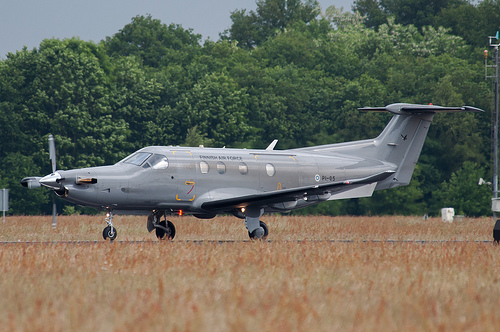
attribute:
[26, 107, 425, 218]
plane — landing, taking off, grey, gray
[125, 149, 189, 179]
windows — round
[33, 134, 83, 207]
propeller — gray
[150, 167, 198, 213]
number — 7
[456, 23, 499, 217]
tower — behind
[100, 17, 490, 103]
trees — green, behind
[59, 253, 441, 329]
grass — burned, burnt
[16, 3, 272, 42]
skies — cloudy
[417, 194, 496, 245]
bucket — white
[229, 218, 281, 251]
wheel — larger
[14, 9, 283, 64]
sky — dark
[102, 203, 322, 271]
wheels — gray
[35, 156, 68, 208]
nose — silver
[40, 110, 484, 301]
airplane — grey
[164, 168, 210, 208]
7 — number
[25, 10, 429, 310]
scene — nice